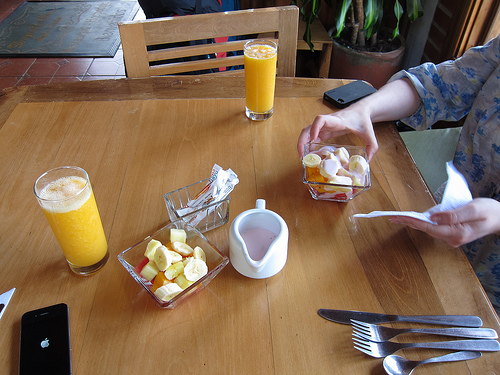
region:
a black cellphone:
[17, 304, 69, 374]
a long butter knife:
[312, 301, 485, 330]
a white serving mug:
[217, 196, 291, 278]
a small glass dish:
[161, 181, 232, 231]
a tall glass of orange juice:
[243, 29, 278, 120]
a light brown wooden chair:
[114, 2, 300, 76]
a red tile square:
[57, 57, 89, 75]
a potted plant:
[322, 0, 414, 90]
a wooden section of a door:
[421, 0, 496, 66]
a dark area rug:
[0, 0, 140, 57]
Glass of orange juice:
[23, 157, 114, 273]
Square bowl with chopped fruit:
[117, 222, 229, 322]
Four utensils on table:
[308, 289, 498, 369]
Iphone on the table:
[9, 301, 84, 373]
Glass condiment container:
[155, 151, 237, 228]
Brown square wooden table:
[25, 80, 148, 165]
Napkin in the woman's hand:
[355, 143, 490, 260]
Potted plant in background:
[319, 0, 422, 83]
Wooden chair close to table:
[108, 1, 325, 97]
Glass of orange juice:
[237, 35, 295, 135]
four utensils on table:
[310, 308, 492, 373]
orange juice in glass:
[27, 158, 126, 283]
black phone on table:
[18, 299, 78, 373]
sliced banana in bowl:
[142, 228, 211, 301]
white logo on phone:
[34, 330, 54, 353]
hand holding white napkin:
[377, 164, 483, 250]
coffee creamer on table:
[220, 187, 302, 289]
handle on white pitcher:
[229, 189, 296, 230]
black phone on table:
[318, 76, 382, 120]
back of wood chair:
[114, 7, 315, 81]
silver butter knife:
[316, 305, 483, 327]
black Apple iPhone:
[19, 299, 71, 374]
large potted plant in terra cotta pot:
[329, 1, 421, 89]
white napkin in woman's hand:
[351, 158, 472, 227]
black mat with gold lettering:
[1, 3, 138, 53]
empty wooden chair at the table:
[117, 4, 299, 81]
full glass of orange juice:
[35, 166, 110, 276]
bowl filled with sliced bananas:
[116, 218, 228, 306]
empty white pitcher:
[227, 197, 289, 277]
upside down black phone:
[323, 78, 376, 108]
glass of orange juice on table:
[235, 30, 287, 133]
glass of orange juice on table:
[26, 143, 113, 290]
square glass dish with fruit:
[118, 221, 227, 321]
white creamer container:
[229, 197, 300, 284]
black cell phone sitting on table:
[12, 300, 77, 372]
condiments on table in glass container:
[155, 162, 240, 233]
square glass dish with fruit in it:
[291, 138, 406, 217]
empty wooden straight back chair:
[113, 2, 320, 104]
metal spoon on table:
[381, 346, 498, 373]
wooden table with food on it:
[37, 48, 242, 222]